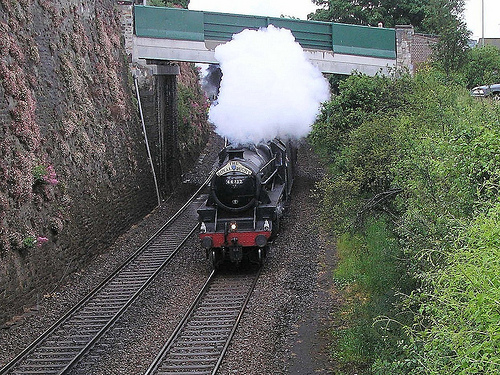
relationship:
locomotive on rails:
[194, 135, 291, 268] [1, 164, 263, 373]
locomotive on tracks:
[194, 135, 291, 268] [2, 259, 137, 373]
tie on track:
[4, 198, 207, 375] [0, 172, 261, 373]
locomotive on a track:
[192, 135, 302, 280] [141, 267, 265, 374]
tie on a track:
[151, 262, 259, 374] [154, 267, 259, 373]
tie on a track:
[4, 198, 207, 375] [154, 267, 259, 373]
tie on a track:
[151, 262, 259, 374] [0, 162, 203, 372]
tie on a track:
[4, 198, 207, 375] [0, 162, 203, 372]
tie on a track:
[179, 337, 226, 342] [0, 162, 203, 372]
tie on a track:
[151, 262, 259, 374] [146, 273, 254, 370]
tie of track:
[75, 287, 125, 311] [74, 240, 318, 365]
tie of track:
[151, 262, 259, 374] [153, 246, 280, 374]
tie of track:
[4, 198, 207, 375] [145, 269, 263, 366]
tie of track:
[189, 310, 238, 321] [141, 267, 265, 374]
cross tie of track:
[177, 330, 219, 359] [185, 286, 247, 368]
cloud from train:
[205, 21, 333, 145] [196, 141, 302, 274]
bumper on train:
[195, 222, 271, 256] [192, 126, 301, 268]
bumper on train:
[195, 223, 272, 253] [190, 96, 316, 280]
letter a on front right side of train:
[261, 218, 271, 229] [195, 79, 300, 276]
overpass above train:
[128, 5, 450, 81] [187, 102, 300, 266]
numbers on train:
[225, 179, 245, 186] [193, 117, 298, 274]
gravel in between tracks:
[46, 279, 271, 354] [0, 115, 314, 373]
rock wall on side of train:
[8, 20, 148, 239] [192, 103, 311, 275]